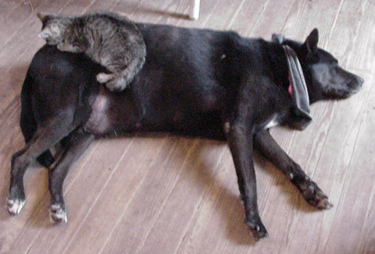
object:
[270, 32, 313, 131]
bandana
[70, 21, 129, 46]
grey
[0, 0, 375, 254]
floor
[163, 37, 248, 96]
black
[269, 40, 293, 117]
neck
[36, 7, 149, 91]
cat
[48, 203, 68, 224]
paws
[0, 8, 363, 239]
dog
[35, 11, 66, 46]
head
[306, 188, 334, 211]
paw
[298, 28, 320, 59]
ear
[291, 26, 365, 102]
head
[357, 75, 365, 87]
nose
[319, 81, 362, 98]
mouth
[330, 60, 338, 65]
eye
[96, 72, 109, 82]
paw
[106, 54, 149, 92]
tail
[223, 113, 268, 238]
leg